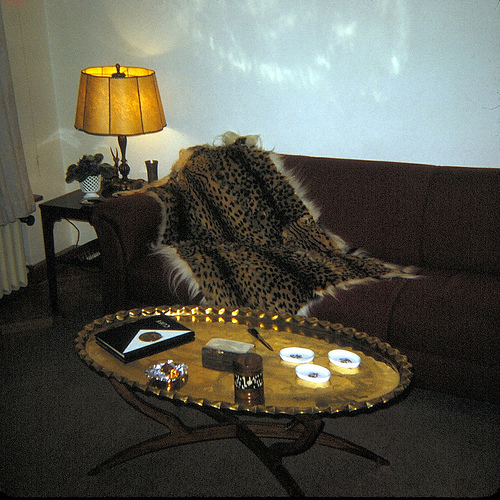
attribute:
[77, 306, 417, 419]
table — oval, real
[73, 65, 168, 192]
light — yellow, on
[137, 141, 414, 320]
fur — spotted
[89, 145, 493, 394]
couch — brown, real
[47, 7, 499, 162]
wall — real, gray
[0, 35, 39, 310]
curtains — whtie, white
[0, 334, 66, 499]
floor — dark